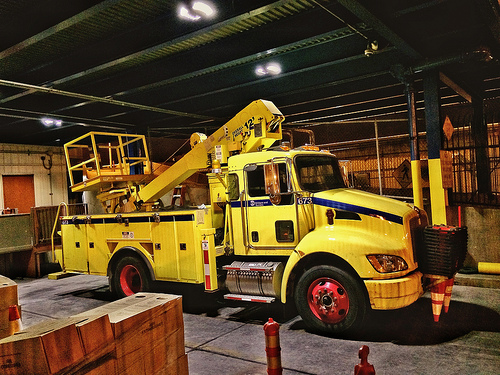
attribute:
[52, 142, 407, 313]
truck — yellow, utility, parked, inside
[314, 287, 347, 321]
rim — red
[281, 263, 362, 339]
tire — black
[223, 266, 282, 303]
item — silver, red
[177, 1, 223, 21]
light — on, overhead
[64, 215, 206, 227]
stripe — blue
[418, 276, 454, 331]
cone — orange, white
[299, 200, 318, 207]
number — 673, white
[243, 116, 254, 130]
number — 12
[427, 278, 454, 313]
cones — hazard, orange, white, stacked, stacks, upside down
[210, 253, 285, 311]
steps — sets, metal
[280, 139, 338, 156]
lights — yellow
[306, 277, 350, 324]
wheel — red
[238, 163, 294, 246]
door — passenger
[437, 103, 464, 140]
sign — yellow, traffic, crossing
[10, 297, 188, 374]
crates — stack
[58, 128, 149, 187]
cage — yellow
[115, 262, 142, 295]
hub cap — red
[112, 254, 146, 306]
wheel — black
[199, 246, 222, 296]
reflectors — white, red